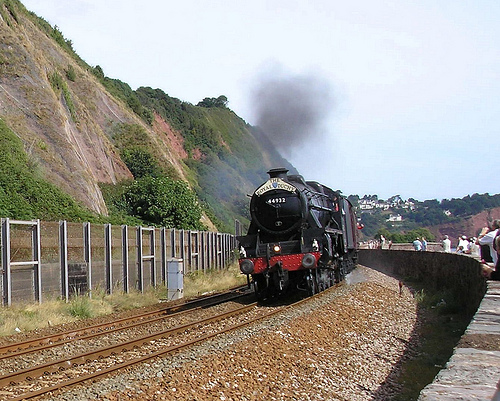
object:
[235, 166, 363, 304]
train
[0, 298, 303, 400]
tracks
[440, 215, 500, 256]
people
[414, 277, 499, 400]
walkway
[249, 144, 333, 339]
smoke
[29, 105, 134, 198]
hill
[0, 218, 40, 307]
wall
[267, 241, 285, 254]
headlight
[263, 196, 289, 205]
number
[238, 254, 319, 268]
plate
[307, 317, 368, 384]
slope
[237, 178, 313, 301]
front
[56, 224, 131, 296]
barrier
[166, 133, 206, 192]
cliff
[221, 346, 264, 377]
gravel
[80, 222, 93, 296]
post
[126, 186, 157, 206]
bushes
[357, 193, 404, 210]
buildings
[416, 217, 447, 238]
hill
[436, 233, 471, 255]
crowd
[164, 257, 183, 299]
box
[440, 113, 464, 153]
sky